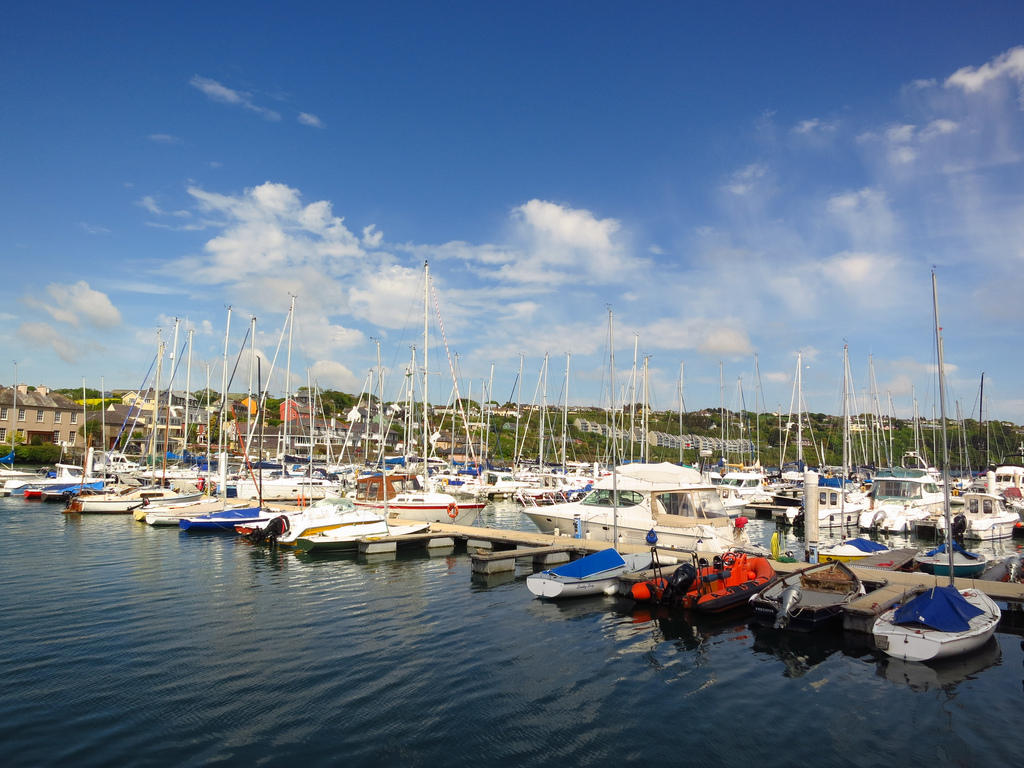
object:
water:
[0, 492, 1024, 768]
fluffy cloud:
[135, 150, 378, 292]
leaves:
[900, 428, 913, 433]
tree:
[882, 429, 901, 467]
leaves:
[550, 412, 555, 416]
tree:
[521, 408, 538, 428]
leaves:
[816, 432, 827, 438]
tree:
[818, 414, 827, 423]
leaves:
[896, 434, 905, 445]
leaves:
[688, 414, 694, 423]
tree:
[670, 411, 714, 430]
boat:
[629, 552, 777, 617]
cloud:
[460, 196, 619, 293]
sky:
[0, 0, 1024, 432]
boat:
[870, 588, 1002, 662]